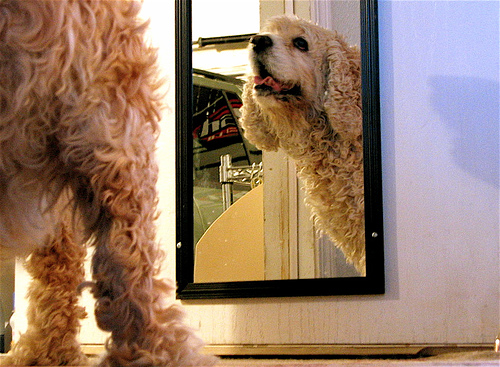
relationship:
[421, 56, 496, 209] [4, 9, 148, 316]
shadow of dog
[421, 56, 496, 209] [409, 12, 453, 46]
shadow on wall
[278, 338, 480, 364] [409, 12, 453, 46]
baseboard on wall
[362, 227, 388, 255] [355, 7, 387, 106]
nails on frame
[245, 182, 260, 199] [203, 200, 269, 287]
corner of table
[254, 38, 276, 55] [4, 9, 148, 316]
nose of dog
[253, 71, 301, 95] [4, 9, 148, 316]
tongue of dog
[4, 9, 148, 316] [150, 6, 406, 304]
dog in mirror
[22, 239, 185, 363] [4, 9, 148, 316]
legs of dog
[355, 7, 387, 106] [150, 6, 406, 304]
frame of mirror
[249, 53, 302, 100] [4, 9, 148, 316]
mouth of dog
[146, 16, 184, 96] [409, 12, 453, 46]
sunlight on wall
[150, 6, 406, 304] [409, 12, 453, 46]
mirror on wall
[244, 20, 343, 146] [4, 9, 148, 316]
face of dog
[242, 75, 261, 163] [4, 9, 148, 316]
right ear of dog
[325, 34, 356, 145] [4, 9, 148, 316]
left ear of dog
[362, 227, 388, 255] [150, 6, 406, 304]
nails on mirror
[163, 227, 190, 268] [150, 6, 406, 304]
nail on left of mirror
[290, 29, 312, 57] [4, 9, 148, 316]
eye of dog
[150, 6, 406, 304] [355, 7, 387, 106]
mirror with frame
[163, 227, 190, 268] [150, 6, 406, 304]
nail in mirror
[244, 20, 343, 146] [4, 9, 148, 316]
head of dog